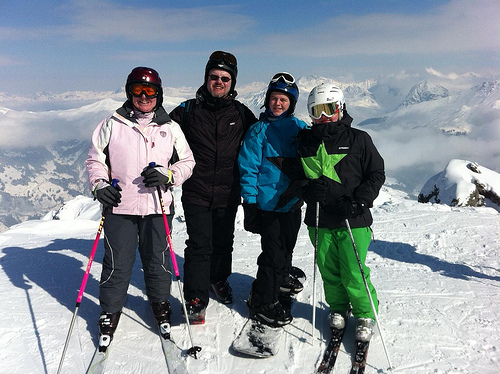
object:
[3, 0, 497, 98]
clouds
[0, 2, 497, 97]
blue sky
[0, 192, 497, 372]
snow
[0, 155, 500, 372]
mountain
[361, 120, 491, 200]
clouds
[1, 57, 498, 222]
mountains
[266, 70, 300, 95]
helmet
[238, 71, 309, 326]
girl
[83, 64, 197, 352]
person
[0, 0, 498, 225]
landscape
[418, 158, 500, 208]
rock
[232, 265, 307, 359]
snowboard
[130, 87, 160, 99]
goggles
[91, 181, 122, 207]
right glove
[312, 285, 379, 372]
ski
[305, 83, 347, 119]
helment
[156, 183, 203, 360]
ski pole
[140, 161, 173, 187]
hand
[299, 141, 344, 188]
star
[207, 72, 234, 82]
sunglasses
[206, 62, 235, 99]
face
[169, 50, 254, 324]
man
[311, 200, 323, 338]
ski pole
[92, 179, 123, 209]
hand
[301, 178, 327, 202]
hand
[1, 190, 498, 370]
hillside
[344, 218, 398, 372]
ski pole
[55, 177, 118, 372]
ski pole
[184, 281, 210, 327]
boot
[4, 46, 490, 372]
top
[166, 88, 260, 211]
ski jacket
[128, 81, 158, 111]
face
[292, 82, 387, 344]
skier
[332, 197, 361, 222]
hand